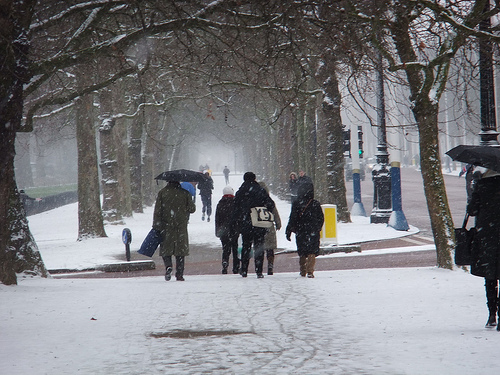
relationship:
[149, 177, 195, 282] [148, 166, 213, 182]
man holding umbrella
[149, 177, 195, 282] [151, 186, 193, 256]
man holding coat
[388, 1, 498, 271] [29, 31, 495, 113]
tree covered with snow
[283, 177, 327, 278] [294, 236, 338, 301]
person wearing boots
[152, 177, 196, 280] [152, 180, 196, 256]
man wearing coat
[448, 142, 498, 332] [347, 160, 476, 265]
person walking street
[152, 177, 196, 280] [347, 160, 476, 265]
man walking street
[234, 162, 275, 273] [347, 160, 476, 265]
person walking street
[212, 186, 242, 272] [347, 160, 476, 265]
person walking street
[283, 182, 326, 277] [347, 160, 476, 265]
person walking street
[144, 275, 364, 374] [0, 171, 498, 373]
tracks in snow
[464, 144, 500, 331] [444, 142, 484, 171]
person carrying umbrella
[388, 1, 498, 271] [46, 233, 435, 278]
tree growing next to sidewalk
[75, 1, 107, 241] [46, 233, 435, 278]
tree growing next to sidewalk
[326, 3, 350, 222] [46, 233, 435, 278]
tree growing next to sidewalk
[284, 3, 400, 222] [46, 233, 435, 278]
tree growing next to sidewalk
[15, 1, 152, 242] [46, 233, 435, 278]
tree growing next to sidewalk